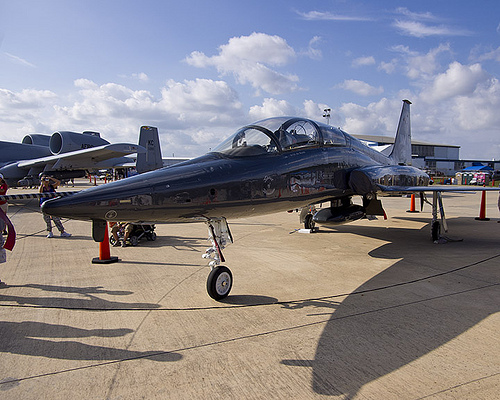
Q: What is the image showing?
A: It is showing an airport.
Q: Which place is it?
A: It is an airport.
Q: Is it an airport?
A: Yes, it is an airport.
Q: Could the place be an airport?
A: Yes, it is an airport.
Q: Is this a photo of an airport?
A: Yes, it is showing an airport.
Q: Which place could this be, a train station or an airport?
A: It is an airport.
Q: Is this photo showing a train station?
A: No, the picture is showing an airport.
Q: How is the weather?
A: It is cloudless.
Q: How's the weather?
A: It is cloudless.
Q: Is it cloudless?
A: Yes, it is cloudless.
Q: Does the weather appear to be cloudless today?
A: Yes, it is cloudless.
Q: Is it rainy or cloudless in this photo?
A: It is cloudless.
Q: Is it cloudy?
A: No, it is cloudless.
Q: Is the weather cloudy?
A: No, it is cloudless.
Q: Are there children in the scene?
A: Yes, there is a child.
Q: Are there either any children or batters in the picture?
A: Yes, there is a child.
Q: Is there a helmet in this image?
A: No, there are no helmets.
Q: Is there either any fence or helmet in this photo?
A: No, there are no helmets or fences.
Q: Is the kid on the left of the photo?
A: Yes, the kid is on the left of the image.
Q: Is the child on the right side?
A: No, the child is on the left of the image.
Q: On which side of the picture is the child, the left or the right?
A: The child is on the left of the image.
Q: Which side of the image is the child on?
A: The child is on the left of the image.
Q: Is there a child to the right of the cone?
A: Yes, there is a child to the right of the cone.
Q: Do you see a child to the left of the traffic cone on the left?
A: No, the child is to the right of the traffic cone.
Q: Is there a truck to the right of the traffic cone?
A: No, there is a child to the right of the traffic cone.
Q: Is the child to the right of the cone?
A: Yes, the child is to the right of the cone.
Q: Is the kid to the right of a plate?
A: No, the kid is to the right of the cone.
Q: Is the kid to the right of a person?
A: Yes, the kid is to the right of a person.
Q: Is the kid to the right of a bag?
A: No, the kid is to the right of a person.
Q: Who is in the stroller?
A: The kid is in the stroller.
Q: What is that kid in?
A: The kid is in the stroller.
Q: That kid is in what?
A: The kid is in the stroller.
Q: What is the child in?
A: The kid is in the stroller.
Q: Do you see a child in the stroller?
A: Yes, there is a child in the stroller.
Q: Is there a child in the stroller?
A: Yes, there is a child in the stroller.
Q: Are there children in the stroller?
A: Yes, there is a child in the stroller.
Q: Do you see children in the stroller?
A: Yes, there is a child in the stroller.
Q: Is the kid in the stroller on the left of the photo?
A: Yes, the kid is in the stroller.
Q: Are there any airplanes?
A: Yes, there is an airplane.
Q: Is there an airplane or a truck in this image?
A: Yes, there is an airplane.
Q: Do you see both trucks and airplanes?
A: No, there is an airplane but no trucks.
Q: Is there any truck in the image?
A: No, there are no trucks.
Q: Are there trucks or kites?
A: No, there are no trucks or kites.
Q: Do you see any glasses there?
A: No, there are no glasses.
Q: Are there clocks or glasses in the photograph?
A: No, there are no glasses or clocks.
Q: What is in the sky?
A: The clouds are in the sky.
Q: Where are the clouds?
A: The clouds are in the sky.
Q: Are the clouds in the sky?
A: Yes, the clouds are in the sky.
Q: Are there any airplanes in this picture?
A: Yes, there is an airplane.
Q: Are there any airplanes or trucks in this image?
A: Yes, there is an airplane.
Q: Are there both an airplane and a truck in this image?
A: No, there is an airplane but no trucks.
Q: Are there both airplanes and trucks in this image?
A: No, there is an airplane but no trucks.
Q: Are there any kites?
A: No, there are no kites.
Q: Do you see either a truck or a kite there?
A: No, there are no kites or trucks.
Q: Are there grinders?
A: No, there are no grinders.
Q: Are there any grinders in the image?
A: No, there are no grinders.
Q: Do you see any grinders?
A: No, there are no grinders.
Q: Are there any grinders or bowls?
A: No, there are no grinders or bowls.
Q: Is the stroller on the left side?
A: Yes, the stroller is on the left of the image.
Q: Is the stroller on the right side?
A: No, the stroller is on the left of the image.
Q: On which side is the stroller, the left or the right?
A: The stroller is on the left of the image.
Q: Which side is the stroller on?
A: The stroller is on the left of the image.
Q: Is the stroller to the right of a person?
A: Yes, the stroller is to the right of a person.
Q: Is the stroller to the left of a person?
A: No, the stroller is to the right of a person.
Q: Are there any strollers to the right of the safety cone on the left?
A: Yes, there is a stroller to the right of the traffic cone.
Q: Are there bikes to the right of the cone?
A: No, there is a stroller to the right of the cone.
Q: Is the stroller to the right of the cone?
A: Yes, the stroller is to the right of the cone.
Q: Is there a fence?
A: No, there are no fences.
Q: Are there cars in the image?
A: No, there are no cars.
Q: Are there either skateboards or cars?
A: No, there are no cars or skateboards.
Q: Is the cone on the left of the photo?
A: Yes, the cone is on the left of the image.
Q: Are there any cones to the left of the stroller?
A: Yes, there is a cone to the left of the stroller.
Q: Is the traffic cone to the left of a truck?
A: No, the traffic cone is to the left of the stroller.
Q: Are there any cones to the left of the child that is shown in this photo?
A: Yes, there is a cone to the left of the child.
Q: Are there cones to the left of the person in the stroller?
A: Yes, there is a cone to the left of the child.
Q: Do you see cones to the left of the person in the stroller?
A: Yes, there is a cone to the left of the child.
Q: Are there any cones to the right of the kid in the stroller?
A: No, the cone is to the left of the kid.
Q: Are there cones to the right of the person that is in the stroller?
A: No, the cone is to the left of the kid.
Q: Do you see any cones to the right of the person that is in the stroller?
A: No, the cone is to the left of the kid.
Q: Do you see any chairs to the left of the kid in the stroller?
A: No, there is a cone to the left of the child.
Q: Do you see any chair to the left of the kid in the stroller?
A: No, there is a cone to the left of the child.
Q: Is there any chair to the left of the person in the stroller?
A: No, there is a cone to the left of the child.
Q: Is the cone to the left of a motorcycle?
A: No, the cone is to the left of the kid.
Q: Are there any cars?
A: No, there are no cars.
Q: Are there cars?
A: No, there are no cars.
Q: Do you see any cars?
A: No, there are no cars.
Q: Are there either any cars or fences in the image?
A: No, there are no cars or fences.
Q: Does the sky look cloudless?
A: Yes, the sky is cloudless.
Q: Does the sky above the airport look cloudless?
A: Yes, the sky is cloudless.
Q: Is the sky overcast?
A: No, the sky is cloudless.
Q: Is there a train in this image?
A: No, there are no trains.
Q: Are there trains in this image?
A: No, there are no trains.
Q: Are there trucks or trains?
A: No, there are no trains or trucks.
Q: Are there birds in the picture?
A: No, there are no birds.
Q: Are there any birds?
A: No, there are no birds.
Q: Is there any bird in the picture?
A: No, there are no birds.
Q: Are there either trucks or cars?
A: No, there are no cars or trucks.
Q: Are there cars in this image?
A: No, there are no cars.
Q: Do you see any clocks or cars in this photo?
A: No, there are no cars or clocks.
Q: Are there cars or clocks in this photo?
A: No, there are no cars or clocks.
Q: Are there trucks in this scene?
A: No, there are no trucks.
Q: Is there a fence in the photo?
A: No, there are no fences.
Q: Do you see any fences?
A: No, there are no fences.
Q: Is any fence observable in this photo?
A: No, there are no fences.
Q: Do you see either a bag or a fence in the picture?
A: No, there are no fences or bags.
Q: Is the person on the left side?
A: Yes, the person is on the left of the image.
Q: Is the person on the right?
A: No, the person is on the left of the image.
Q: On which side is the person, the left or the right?
A: The person is on the left of the image.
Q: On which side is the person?
A: The person is on the left of the image.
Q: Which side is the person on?
A: The person is on the left of the image.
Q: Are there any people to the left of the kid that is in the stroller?
A: Yes, there is a person to the left of the child.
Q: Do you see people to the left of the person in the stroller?
A: Yes, there is a person to the left of the child.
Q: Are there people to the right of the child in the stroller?
A: No, the person is to the left of the kid.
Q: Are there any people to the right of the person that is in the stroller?
A: No, the person is to the left of the kid.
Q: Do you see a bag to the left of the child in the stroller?
A: No, there is a person to the left of the kid.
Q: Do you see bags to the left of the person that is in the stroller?
A: No, there is a person to the left of the kid.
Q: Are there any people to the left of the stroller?
A: Yes, there is a person to the left of the stroller.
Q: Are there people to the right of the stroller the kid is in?
A: No, the person is to the left of the stroller.